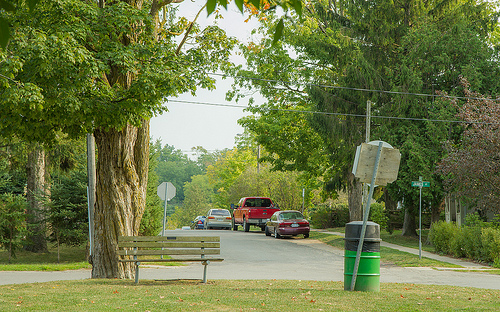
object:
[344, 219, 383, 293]
trash can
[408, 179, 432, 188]
sign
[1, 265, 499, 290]
road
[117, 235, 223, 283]
bench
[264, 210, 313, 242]
car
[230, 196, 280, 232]
car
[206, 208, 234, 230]
car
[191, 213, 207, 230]
car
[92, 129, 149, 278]
trunk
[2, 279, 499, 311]
grass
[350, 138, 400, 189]
sign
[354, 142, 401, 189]
wooden block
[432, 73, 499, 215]
tree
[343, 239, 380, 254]
bag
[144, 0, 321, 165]
sky